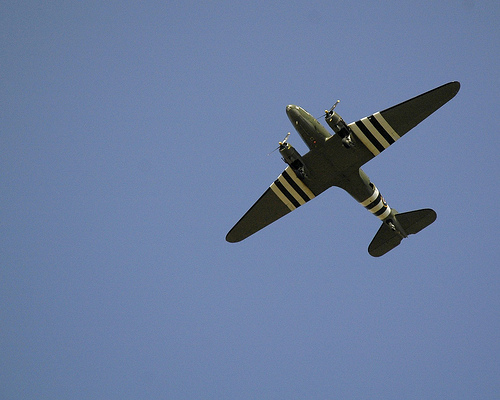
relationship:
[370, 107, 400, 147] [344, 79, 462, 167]
stripe on underside of wing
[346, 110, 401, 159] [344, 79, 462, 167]
stripe on underside of wing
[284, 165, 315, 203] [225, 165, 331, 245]
stripe on underside of wing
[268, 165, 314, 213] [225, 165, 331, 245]
stripe on underside of wing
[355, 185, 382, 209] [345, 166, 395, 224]
stripe on body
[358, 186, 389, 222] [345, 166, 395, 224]
stripe on body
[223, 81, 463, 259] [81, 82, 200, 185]
airplane flying through sky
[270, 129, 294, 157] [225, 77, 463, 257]
propeller on plane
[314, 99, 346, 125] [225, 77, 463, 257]
propeller on plane